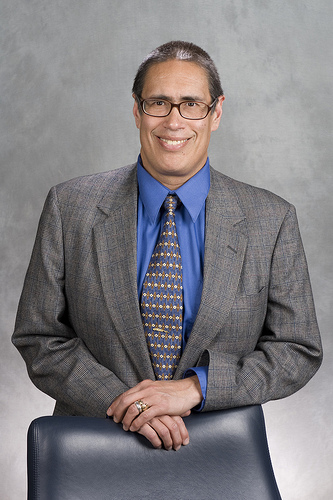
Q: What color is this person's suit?
A: Gray.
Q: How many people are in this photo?
A: One.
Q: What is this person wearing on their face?
A: Glasses.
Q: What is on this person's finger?
A: Two rings.